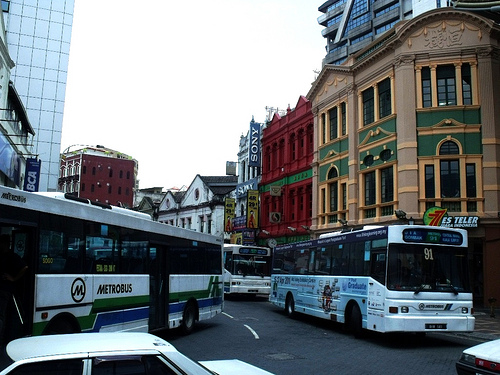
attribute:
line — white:
[243, 322, 261, 341]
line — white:
[220, 308, 234, 319]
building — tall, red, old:
[259, 94, 313, 248]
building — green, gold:
[306, 7, 498, 309]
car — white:
[0, 330, 278, 374]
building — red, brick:
[60, 143, 140, 206]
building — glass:
[2, 0, 77, 192]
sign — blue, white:
[248, 121, 262, 166]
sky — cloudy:
[63, 0, 326, 191]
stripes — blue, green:
[78, 288, 223, 331]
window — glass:
[45, 20, 65, 43]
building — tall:
[314, 0, 409, 66]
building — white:
[155, 172, 243, 234]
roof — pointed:
[183, 172, 242, 206]